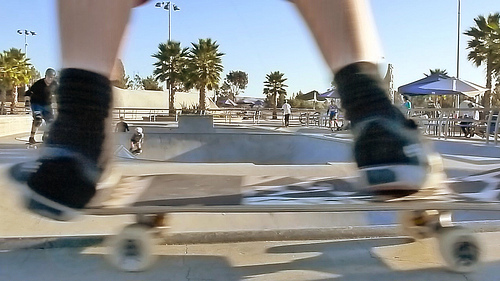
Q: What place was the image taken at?
A: It was taken at the park.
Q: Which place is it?
A: It is a park.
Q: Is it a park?
A: Yes, it is a park.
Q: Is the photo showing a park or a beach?
A: It is showing a park.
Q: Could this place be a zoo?
A: No, it is a park.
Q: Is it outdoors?
A: Yes, it is outdoors.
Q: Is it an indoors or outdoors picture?
A: It is outdoors.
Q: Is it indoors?
A: No, it is outdoors.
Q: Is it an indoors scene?
A: No, it is outdoors.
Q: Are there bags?
A: No, there are no bags.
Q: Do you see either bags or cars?
A: No, there are no bags or cars.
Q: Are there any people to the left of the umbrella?
A: Yes, there is a person to the left of the umbrella.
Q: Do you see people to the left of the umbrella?
A: Yes, there is a person to the left of the umbrella.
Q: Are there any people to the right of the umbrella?
A: No, the person is to the left of the umbrella.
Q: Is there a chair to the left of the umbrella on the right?
A: No, there is a person to the left of the umbrella.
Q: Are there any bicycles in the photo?
A: Yes, there is a bicycle.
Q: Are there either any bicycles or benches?
A: Yes, there is a bicycle.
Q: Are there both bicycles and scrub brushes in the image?
A: No, there is a bicycle but no scrub brushes.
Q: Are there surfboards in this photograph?
A: No, there are no surfboards.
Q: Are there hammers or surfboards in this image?
A: No, there are no surfboards or hammers.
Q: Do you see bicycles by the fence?
A: Yes, there is a bicycle by the fence.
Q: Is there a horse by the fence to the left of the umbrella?
A: No, there is a bicycle by the fence.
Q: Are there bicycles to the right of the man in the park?
A: Yes, there is a bicycle to the right of the man.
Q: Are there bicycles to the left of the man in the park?
A: No, the bicycle is to the right of the man.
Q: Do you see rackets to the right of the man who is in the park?
A: No, there is a bicycle to the right of the man.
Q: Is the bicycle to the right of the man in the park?
A: Yes, the bicycle is to the right of the man.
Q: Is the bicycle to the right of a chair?
A: No, the bicycle is to the right of the man.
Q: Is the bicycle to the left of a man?
A: No, the bicycle is to the right of a man.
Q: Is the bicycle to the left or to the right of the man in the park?
A: The bicycle is to the right of the man.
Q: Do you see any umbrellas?
A: Yes, there is an umbrella.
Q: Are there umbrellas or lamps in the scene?
A: Yes, there is an umbrella.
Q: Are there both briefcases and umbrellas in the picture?
A: No, there is an umbrella but no briefcases.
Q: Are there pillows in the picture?
A: No, there are no pillows.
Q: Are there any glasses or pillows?
A: No, there are no pillows or glasses.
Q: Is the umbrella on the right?
A: Yes, the umbrella is on the right of the image.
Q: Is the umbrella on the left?
A: No, the umbrella is on the right of the image.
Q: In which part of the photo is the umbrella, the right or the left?
A: The umbrella is on the right of the image.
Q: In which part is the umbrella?
A: The umbrella is on the right of the image.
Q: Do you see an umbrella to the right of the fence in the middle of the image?
A: Yes, there is an umbrella to the right of the fence.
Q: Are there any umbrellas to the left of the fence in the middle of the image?
A: No, the umbrella is to the right of the fence.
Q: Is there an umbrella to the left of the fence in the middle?
A: No, the umbrella is to the right of the fence.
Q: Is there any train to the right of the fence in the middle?
A: No, there is an umbrella to the right of the fence.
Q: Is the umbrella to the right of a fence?
A: Yes, the umbrella is to the right of a fence.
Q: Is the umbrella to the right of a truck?
A: No, the umbrella is to the right of a fence.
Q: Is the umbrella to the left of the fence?
A: No, the umbrella is to the right of the fence.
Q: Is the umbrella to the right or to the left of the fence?
A: The umbrella is to the right of the fence.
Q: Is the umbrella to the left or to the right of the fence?
A: The umbrella is to the right of the fence.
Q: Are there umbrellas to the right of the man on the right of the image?
A: Yes, there is an umbrella to the right of the man.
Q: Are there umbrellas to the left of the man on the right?
A: No, the umbrella is to the right of the man.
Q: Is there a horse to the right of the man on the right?
A: No, there is an umbrella to the right of the man.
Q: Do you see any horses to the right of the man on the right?
A: No, there is an umbrella to the right of the man.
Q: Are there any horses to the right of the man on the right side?
A: No, there is an umbrella to the right of the man.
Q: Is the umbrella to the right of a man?
A: Yes, the umbrella is to the right of a man.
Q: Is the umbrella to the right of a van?
A: No, the umbrella is to the right of a man.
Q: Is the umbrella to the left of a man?
A: No, the umbrella is to the right of a man.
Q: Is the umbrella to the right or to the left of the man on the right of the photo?
A: The umbrella is to the right of the man.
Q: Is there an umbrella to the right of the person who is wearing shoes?
A: Yes, there is an umbrella to the right of the person.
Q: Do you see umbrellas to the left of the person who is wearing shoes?
A: No, the umbrella is to the right of the person.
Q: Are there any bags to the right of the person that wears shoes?
A: No, there is an umbrella to the right of the person.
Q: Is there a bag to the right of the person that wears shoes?
A: No, there is an umbrella to the right of the person.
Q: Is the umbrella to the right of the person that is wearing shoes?
A: Yes, the umbrella is to the right of the person.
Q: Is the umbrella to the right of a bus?
A: No, the umbrella is to the right of the person.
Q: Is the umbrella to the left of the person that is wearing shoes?
A: No, the umbrella is to the right of the person.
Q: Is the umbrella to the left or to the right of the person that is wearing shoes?
A: The umbrella is to the right of the person.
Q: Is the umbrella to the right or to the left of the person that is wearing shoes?
A: The umbrella is to the right of the person.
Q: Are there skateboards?
A: Yes, there is a skateboard.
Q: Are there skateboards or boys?
A: Yes, there is a skateboard.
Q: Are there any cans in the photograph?
A: No, there are no cans.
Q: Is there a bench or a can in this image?
A: No, there are no cans or benches.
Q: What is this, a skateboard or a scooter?
A: This is a skateboard.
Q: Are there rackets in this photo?
A: No, there are no rackets.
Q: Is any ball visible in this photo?
A: No, there are no balls.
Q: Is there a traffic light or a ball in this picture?
A: No, there are no balls or traffic lights.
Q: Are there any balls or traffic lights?
A: No, there are no balls or traffic lights.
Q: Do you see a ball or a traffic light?
A: No, there are no balls or traffic lights.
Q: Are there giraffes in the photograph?
A: No, there are no giraffes.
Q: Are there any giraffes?
A: No, there are no giraffes.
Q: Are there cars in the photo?
A: No, there are no cars.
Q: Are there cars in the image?
A: No, there are no cars.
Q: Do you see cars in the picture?
A: No, there are no cars.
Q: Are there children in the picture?
A: Yes, there is a child.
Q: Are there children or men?
A: Yes, there is a child.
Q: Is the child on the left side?
A: Yes, the child is on the left of the image.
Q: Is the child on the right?
A: No, the child is on the left of the image.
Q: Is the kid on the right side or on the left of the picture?
A: The kid is on the left of the image.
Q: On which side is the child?
A: The child is on the left of the image.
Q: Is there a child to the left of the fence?
A: Yes, there is a child to the left of the fence.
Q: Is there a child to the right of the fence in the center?
A: No, the child is to the left of the fence.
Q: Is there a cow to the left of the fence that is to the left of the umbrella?
A: No, there is a child to the left of the fence.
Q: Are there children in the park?
A: Yes, there is a child in the park.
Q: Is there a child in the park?
A: Yes, there is a child in the park.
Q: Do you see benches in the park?
A: No, there is a child in the park.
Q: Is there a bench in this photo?
A: No, there are no benches.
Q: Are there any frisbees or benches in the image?
A: No, there are no benches or frisbees.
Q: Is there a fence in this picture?
A: Yes, there is a fence.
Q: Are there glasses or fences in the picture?
A: Yes, there is a fence.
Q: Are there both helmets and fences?
A: Yes, there are both a fence and a helmet.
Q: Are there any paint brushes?
A: No, there are no paint brushes.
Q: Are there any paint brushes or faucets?
A: No, there are no paint brushes or faucets.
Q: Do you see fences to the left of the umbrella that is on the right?
A: Yes, there is a fence to the left of the umbrella.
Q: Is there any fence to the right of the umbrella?
A: No, the fence is to the left of the umbrella.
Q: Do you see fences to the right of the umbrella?
A: No, the fence is to the left of the umbrella.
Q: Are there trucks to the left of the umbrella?
A: No, there is a fence to the left of the umbrella.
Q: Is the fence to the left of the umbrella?
A: Yes, the fence is to the left of the umbrella.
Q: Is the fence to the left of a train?
A: No, the fence is to the left of the umbrella.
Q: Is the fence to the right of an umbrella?
A: No, the fence is to the left of an umbrella.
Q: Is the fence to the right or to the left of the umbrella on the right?
A: The fence is to the left of the umbrella.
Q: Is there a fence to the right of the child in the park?
A: Yes, there is a fence to the right of the child.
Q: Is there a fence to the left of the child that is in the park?
A: No, the fence is to the right of the child.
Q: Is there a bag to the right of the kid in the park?
A: No, there is a fence to the right of the child.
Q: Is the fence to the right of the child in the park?
A: Yes, the fence is to the right of the child.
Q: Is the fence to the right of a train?
A: No, the fence is to the right of the child.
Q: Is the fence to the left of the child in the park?
A: No, the fence is to the right of the kid.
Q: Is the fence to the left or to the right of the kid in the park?
A: The fence is to the right of the kid.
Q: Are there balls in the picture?
A: No, there are no balls.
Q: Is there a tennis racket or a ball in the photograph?
A: No, there are no balls or rackets.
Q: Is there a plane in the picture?
A: No, there are no airplanes.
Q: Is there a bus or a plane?
A: No, there are no airplanes or buses.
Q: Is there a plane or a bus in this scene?
A: No, there are no airplanes or buses.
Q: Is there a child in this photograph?
A: Yes, there is a child.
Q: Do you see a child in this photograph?
A: Yes, there is a child.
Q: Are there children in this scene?
A: Yes, there is a child.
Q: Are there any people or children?
A: Yes, there is a child.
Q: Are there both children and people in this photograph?
A: Yes, there are both a child and people.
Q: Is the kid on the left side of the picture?
A: Yes, the kid is on the left of the image.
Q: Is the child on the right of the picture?
A: No, the child is on the left of the image.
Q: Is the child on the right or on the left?
A: The child is on the left of the image.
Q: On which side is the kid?
A: The kid is on the left of the image.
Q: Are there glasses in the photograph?
A: No, there are no glasses.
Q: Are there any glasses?
A: No, there are no glasses.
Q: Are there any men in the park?
A: Yes, there is a man in the park.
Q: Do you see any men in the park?
A: Yes, there is a man in the park.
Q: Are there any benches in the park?
A: No, there is a man in the park.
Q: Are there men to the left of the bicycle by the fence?
A: Yes, there is a man to the left of the bicycle.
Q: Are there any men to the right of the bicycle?
A: No, the man is to the left of the bicycle.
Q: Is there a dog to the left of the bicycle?
A: No, there is a man to the left of the bicycle.